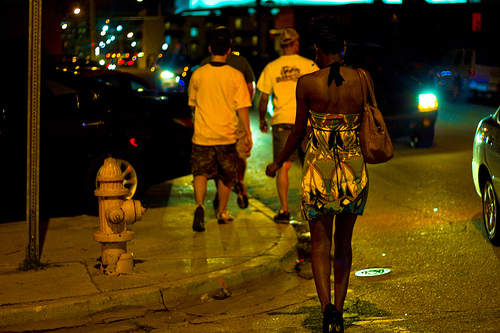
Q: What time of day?
A: Nighttime.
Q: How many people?
A: Three.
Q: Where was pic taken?
A: A busy street.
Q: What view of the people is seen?
A: Back view.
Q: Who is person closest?
A: A woman.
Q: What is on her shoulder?
A: A purse.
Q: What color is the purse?
A: Brown.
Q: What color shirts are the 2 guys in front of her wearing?
A: White.